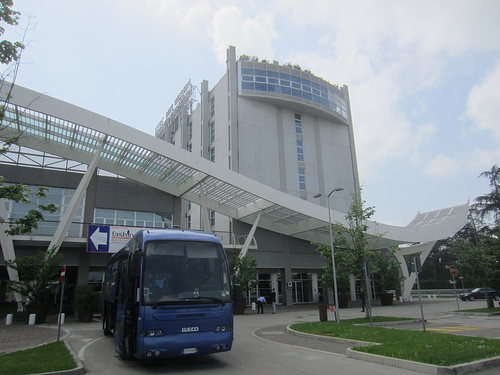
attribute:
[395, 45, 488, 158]
clouds — white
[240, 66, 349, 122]
windows — curved, glass 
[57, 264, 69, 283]
sign — caution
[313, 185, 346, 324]
light pole — tall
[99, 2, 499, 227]
clouds — white, blue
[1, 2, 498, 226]
sky — blue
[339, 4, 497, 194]
clouds — white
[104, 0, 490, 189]
sky — blue 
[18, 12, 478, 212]
sky — blue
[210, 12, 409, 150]
clouds — white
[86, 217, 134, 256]
arrow — white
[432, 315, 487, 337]
street sign — painted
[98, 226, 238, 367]
bus — blue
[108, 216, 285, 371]
bus — blue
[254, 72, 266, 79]
window — glass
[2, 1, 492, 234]
cloud — WHITE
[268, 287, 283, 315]
person — standing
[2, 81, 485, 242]
ramp — curved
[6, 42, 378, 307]
building — tall  and white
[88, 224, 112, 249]
arrow — directional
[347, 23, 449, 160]
clouds — white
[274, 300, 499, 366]
island — curved, grass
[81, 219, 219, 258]
sign — elevated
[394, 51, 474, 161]
sky — blue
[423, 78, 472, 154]
sky — BLUE